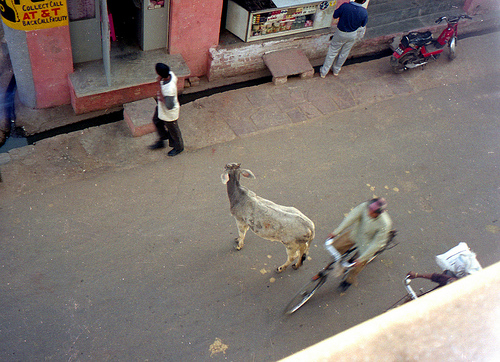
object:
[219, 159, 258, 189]
head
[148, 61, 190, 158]
man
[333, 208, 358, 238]
sleeves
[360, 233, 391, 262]
sleeves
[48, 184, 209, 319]
street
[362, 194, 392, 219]
head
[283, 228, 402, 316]
bicycle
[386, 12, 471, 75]
bike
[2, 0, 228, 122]
storefront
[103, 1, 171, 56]
doorway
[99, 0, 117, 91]
metal/gray pole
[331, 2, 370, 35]
shirt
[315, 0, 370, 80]
person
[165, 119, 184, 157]
legs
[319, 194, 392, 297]
person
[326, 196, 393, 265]
shirt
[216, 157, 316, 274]
animal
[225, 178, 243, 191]
neck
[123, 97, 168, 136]
step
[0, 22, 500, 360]
road